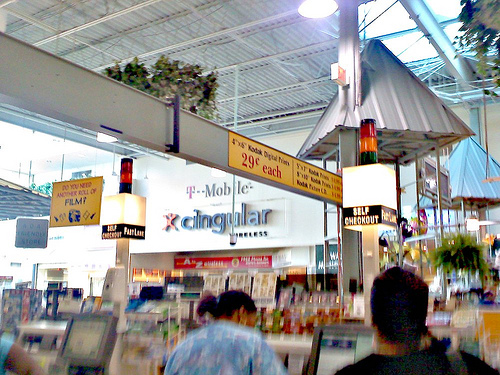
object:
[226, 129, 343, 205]
sign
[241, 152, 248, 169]
numbers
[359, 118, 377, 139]
lights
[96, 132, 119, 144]
light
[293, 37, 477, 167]
roof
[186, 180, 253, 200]
logos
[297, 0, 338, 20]
light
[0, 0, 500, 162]
roof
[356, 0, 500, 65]
skylight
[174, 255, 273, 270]
sign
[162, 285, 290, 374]
woman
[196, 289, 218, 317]
ponytail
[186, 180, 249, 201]
t mobile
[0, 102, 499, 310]
wall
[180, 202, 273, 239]
cingular wireless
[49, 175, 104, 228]
sign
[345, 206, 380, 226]
self checkout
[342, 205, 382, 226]
sign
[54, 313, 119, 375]
cash register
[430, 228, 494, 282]
plant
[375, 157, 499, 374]
store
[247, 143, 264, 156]
kodak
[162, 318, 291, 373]
shirt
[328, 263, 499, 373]
people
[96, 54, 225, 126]
plants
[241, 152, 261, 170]
29 cents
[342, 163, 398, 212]
light